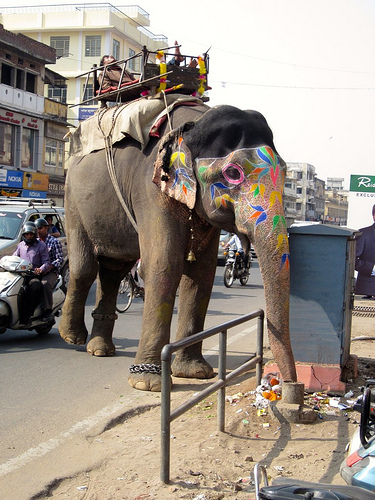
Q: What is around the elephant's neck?
A: A bell.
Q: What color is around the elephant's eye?
A: Purple.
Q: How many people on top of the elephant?
A: One.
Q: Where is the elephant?
A: In a street.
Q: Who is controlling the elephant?
A: A man.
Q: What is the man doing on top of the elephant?
A: Sleeping.